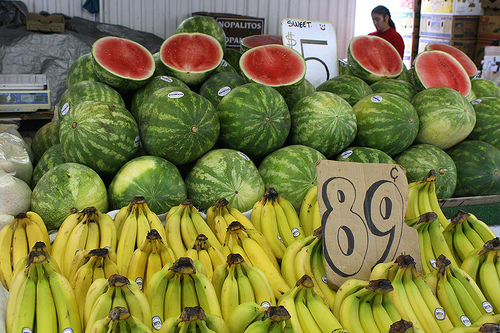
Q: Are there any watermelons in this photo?
A: Yes, there is a watermelon.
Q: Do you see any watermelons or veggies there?
A: Yes, there is a watermelon.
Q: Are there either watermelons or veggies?
A: Yes, there is a watermelon.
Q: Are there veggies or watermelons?
A: Yes, there is a watermelon.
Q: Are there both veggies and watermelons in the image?
A: No, there is a watermelon but no vegetables.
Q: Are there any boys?
A: No, there are no boys.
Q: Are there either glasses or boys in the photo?
A: No, there are no boys or glasses.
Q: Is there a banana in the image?
A: Yes, there is a banana.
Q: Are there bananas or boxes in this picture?
A: Yes, there is a banana.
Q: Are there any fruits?
A: Yes, there is a fruit.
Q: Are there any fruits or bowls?
A: Yes, there is a fruit.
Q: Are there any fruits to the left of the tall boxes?
A: Yes, there is a fruit to the left of the boxes.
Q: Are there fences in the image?
A: No, there are no fences.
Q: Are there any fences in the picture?
A: No, there are no fences.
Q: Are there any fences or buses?
A: No, there are no fences or buses.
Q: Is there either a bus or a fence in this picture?
A: No, there are no fences or buses.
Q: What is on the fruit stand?
A: The sign is on the fruit stand.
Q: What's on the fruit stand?
A: The sign is on the fruit stand.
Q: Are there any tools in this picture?
A: No, there are no tools.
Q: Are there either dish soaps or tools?
A: No, there are no tools or dish soaps.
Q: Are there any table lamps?
A: No, there are no table lamps.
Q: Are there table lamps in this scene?
A: No, there are no table lamps.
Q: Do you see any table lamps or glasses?
A: No, there are no table lamps or glasses.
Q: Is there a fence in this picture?
A: No, there are no fences.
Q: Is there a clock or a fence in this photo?
A: No, there are no fences or clocks.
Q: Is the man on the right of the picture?
A: Yes, the man is on the right of the image.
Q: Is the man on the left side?
A: No, the man is on the right of the image.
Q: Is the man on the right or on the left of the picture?
A: The man is on the right of the image.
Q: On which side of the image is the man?
A: The man is on the right of the image.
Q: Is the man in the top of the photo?
A: Yes, the man is in the top of the image.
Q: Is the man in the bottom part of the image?
A: No, the man is in the top of the image.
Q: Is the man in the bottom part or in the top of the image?
A: The man is in the top of the image.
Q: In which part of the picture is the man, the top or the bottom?
A: The man is in the top of the image.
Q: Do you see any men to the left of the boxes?
A: Yes, there is a man to the left of the boxes.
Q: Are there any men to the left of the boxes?
A: Yes, there is a man to the left of the boxes.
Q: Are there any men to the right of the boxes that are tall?
A: No, the man is to the left of the boxes.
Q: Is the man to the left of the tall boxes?
A: Yes, the man is to the left of the boxes.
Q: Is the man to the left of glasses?
A: No, the man is to the left of the boxes.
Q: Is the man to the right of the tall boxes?
A: No, the man is to the left of the boxes.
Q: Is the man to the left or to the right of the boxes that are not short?
A: The man is to the left of the boxes.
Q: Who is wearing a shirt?
A: The man is wearing a shirt.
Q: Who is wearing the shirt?
A: The man is wearing a shirt.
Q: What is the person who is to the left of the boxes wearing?
A: The man is wearing a shirt.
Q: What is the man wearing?
A: The man is wearing a shirt.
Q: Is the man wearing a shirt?
A: Yes, the man is wearing a shirt.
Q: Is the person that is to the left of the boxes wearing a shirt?
A: Yes, the man is wearing a shirt.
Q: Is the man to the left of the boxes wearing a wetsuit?
A: No, the man is wearing a shirt.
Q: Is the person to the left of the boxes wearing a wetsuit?
A: No, the man is wearing a shirt.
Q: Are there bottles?
A: No, there are no bottles.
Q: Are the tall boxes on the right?
A: Yes, the boxes are on the right of the image.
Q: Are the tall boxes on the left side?
A: No, the boxes are on the right of the image.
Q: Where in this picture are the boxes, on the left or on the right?
A: The boxes are on the right of the image.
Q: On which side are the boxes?
A: The boxes are on the right of the image.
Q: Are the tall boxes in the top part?
A: Yes, the boxes are in the top of the image.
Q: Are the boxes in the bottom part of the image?
A: No, the boxes are in the top of the image.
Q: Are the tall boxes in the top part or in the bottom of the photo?
A: The boxes are in the top of the image.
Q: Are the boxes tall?
A: Yes, the boxes are tall.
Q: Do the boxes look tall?
A: Yes, the boxes are tall.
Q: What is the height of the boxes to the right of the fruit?
A: The boxes are tall.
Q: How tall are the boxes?
A: The boxes are tall.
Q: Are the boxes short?
A: No, the boxes are tall.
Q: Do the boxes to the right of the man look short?
A: No, the boxes are tall.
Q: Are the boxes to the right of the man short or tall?
A: The boxes are tall.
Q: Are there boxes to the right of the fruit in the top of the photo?
A: Yes, there are boxes to the right of the fruit.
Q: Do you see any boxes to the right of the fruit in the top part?
A: Yes, there are boxes to the right of the fruit.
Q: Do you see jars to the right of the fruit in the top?
A: No, there are boxes to the right of the fruit.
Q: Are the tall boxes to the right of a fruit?
A: Yes, the boxes are to the right of a fruit.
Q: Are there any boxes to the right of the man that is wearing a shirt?
A: Yes, there are boxes to the right of the man.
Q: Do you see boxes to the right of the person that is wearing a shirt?
A: Yes, there are boxes to the right of the man.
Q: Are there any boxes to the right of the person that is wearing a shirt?
A: Yes, there are boxes to the right of the man.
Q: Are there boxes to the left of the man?
A: No, the boxes are to the right of the man.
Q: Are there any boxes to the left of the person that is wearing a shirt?
A: No, the boxes are to the right of the man.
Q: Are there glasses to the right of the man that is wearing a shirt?
A: No, there are boxes to the right of the man.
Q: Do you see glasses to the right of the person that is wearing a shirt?
A: No, there are boxes to the right of the man.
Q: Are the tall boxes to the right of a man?
A: Yes, the boxes are to the right of a man.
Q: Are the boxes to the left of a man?
A: No, the boxes are to the right of a man.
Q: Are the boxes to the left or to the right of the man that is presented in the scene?
A: The boxes are to the right of the man.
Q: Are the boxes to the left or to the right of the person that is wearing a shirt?
A: The boxes are to the right of the man.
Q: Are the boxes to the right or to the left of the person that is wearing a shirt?
A: The boxes are to the right of the man.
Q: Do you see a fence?
A: No, there are no fences.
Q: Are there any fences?
A: No, there are no fences.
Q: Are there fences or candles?
A: No, there are no fences or candles.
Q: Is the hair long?
A: Yes, the hair is long.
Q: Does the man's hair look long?
A: Yes, the hair is long.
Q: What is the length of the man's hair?
A: The hair is long.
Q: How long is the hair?
A: The hair is long.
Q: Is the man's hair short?
A: No, the hair is long.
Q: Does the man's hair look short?
A: No, the hair is long.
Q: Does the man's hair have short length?
A: No, the hair is long.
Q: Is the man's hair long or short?
A: The hair is long.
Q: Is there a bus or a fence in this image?
A: No, there are no fences or buses.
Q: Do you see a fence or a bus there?
A: No, there are no fences or buses.